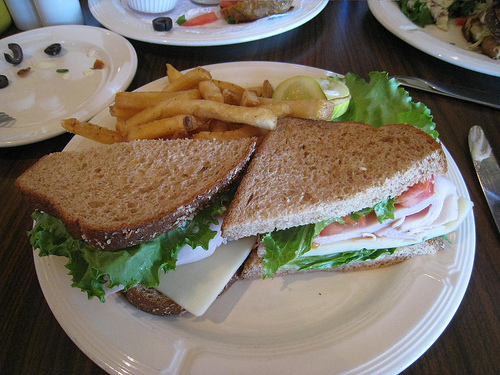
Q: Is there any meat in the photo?
A: Yes, there is meat.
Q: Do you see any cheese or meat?
A: Yes, there is meat.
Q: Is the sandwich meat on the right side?
A: Yes, the meat is on the right of the image.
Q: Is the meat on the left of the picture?
A: No, the meat is on the right of the image.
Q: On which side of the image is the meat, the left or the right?
A: The meat is on the right of the image.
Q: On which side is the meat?
A: The meat is on the right of the image.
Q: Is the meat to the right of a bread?
A: Yes, the meat is to the right of a bread.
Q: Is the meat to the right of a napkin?
A: No, the meat is to the right of a bread.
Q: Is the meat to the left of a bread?
A: No, the meat is to the right of a bread.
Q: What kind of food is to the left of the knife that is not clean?
A: The food is meat.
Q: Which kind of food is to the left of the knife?
A: The food is meat.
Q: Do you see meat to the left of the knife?
A: Yes, there is meat to the left of the knife.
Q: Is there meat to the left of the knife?
A: Yes, there is meat to the left of the knife.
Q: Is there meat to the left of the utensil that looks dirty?
A: Yes, there is meat to the left of the knife.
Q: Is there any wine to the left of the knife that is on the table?
A: No, there is meat to the left of the knife.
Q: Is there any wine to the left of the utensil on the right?
A: No, there is meat to the left of the knife.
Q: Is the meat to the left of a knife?
A: Yes, the meat is to the left of a knife.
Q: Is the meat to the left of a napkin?
A: No, the meat is to the left of a knife.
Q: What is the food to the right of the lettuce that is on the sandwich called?
A: The food is meat.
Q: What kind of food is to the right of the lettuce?
A: The food is meat.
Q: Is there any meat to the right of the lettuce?
A: Yes, there is meat to the right of the lettuce.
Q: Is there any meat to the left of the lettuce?
A: No, the meat is to the right of the lettuce.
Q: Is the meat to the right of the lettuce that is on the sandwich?
A: Yes, the meat is to the right of the lettuce.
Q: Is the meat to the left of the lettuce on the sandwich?
A: No, the meat is to the right of the lettuce.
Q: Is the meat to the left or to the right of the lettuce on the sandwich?
A: The meat is to the right of the lettuce.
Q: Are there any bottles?
A: No, there are no bottles.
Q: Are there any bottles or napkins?
A: No, there are no bottles or napkins.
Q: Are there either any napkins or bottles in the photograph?
A: No, there are no bottles or napkins.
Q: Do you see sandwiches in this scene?
A: Yes, there is a sandwich.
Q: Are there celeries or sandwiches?
A: Yes, there is a sandwich.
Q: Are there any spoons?
A: No, there are no spoons.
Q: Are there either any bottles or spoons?
A: No, there are no spoons or bottles.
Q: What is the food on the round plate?
A: The food is a sandwich.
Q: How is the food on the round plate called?
A: The food is a sandwich.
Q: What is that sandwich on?
A: The sandwich is on the plate.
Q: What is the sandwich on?
A: The sandwich is on the plate.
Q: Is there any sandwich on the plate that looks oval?
A: Yes, there is a sandwich on the plate.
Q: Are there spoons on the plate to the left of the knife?
A: No, there is a sandwich on the plate.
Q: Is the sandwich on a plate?
A: Yes, the sandwich is on a plate.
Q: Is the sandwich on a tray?
A: No, the sandwich is on a plate.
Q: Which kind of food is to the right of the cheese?
A: The food is a sandwich.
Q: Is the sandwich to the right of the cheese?
A: Yes, the sandwich is to the right of the cheese.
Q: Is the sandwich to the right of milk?
A: No, the sandwich is to the right of the cheese.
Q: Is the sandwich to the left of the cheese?
A: No, the sandwich is to the right of the cheese.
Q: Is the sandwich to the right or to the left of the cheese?
A: The sandwich is to the right of the cheese.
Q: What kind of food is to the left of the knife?
A: The food is a sandwich.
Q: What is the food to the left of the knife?
A: The food is a sandwich.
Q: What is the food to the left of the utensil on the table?
A: The food is a sandwich.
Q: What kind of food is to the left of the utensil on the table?
A: The food is a sandwich.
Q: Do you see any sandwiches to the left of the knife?
A: Yes, there is a sandwich to the left of the knife.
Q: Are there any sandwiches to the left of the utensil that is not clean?
A: Yes, there is a sandwich to the left of the knife.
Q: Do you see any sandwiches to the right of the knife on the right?
A: No, the sandwich is to the left of the knife.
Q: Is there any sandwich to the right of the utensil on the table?
A: No, the sandwich is to the left of the knife.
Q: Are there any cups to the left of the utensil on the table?
A: No, there is a sandwich to the left of the knife.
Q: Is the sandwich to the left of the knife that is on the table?
A: Yes, the sandwich is to the left of the knife.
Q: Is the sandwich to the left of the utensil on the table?
A: Yes, the sandwich is to the left of the knife.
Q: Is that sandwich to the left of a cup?
A: No, the sandwich is to the left of the knife.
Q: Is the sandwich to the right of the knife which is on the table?
A: No, the sandwich is to the left of the knife.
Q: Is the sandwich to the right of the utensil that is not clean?
A: No, the sandwich is to the left of the knife.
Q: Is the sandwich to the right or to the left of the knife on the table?
A: The sandwich is to the left of the knife.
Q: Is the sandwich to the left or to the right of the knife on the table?
A: The sandwich is to the left of the knife.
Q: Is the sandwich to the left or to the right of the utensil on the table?
A: The sandwich is to the left of the knife.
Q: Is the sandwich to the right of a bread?
A: Yes, the sandwich is to the right of a bread.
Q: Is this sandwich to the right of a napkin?
A: No, the sandwich is to the right of a bread.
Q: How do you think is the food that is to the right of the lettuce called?
A: The food is a sandwich.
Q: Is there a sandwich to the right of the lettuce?
A: Yes, there is a sandwich to the right of the lettuce.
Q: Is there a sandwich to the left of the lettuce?
A: No, the sandwich is to the right of the lettuce.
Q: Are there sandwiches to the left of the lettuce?
A: No, the sandwich is to the right of the lettuce.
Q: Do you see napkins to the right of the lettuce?
A: No, there is a sandwich to the right of the lettuce.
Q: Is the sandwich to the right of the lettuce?
A: Yes, the sandwich is to the right of the lettuce.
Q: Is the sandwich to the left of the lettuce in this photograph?
A: No, the sandwich is to the right of the lettuce.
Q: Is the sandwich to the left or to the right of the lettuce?
A: The sandwich is to the right of the lettuce.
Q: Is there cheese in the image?
A: Yes, there is cheese.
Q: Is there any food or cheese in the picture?
A: Yes, there is cheese.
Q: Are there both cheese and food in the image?
A: Yes, there are both cheese and food.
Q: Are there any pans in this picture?
A: No, there are no pans.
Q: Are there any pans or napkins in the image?
A: No, there are no pans or napkins.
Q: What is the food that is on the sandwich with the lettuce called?
A: The food is cheese.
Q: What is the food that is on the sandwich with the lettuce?
A: The food is cheese.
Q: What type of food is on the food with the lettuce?
A: The food is cheese.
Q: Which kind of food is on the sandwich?
A: The food is cheese.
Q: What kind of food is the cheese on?
A: The cheese is on the sandwich.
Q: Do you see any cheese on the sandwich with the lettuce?
A: Yes, there is cheese on the sandwich.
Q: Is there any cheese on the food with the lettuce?
A: Yes, there is cheese on the sandwich.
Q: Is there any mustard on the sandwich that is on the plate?
A: No, there is cheese on the sandwich.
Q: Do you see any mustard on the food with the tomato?
A: No, there is cheese on the sandwich.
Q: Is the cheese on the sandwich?
A: Yes, the cheese is on the sandwich.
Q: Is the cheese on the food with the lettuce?
A: Yes, the cheese is on the sandwich.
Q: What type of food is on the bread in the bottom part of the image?
A: The food is cheese.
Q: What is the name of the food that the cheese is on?
A: The food is a bread.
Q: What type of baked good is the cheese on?
A: The cheese is on the bread.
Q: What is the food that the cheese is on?
A: The food is a bread.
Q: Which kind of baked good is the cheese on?
A: The cheese is on the bread.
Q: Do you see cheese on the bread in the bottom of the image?
A: Yes, there is cheese on the bread.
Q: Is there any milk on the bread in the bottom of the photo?
A: No, there is cheese on the bread.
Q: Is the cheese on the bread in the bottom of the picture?
A: Yes, the cheese is on the bread.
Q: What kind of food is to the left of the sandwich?
A: The food is cheese.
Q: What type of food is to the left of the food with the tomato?
A: The food is cheese.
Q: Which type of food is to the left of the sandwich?
A: The food is cheese.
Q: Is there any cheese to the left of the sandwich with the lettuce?
A: Yes, there is cheese to the left of the sandwich.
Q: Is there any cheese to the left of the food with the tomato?
A: Yes, there is cheese to the left of the sandwich.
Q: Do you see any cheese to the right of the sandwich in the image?
A: No, the cheese is to the left of the sandwich.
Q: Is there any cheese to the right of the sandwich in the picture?
A: No, the cheese is to the left of the sandwich.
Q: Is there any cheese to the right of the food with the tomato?
A: No, the cheese is to the left of the sandwich.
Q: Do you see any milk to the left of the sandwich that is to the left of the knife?
A: No, there is cheese to the left of the sandwich.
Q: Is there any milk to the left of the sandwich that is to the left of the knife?
A: No, there is cheese to the left of the sandwich.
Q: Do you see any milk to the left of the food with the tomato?
A: No, there is cheese to the left of the sandwich.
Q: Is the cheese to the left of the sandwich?
A: Yes, the cheese is to the left of the sandwich.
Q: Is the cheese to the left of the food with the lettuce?
A: Yes, the cheese is to the left of the sandwich.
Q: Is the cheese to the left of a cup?
A: No, the cheese is to the left of the sandwich.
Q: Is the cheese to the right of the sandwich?
A: No, the cheese is to the left of the sandwich.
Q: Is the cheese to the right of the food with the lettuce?
A: No, the cheese is to the left of the sandwich.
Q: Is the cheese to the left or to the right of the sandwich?
A: The cheese is to the left of the sandwich.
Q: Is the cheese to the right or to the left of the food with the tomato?
A: The cheese is to the left of the sandwich.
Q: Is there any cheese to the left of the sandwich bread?
A: Yes, there is cheese to the left of the bread.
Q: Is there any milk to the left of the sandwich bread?
A: No, there is cheese to the left of the bread.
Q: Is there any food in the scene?
A: Yes, there is food.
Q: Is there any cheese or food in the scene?
A: Yes, there is food.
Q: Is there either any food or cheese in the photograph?
A: Yes, there is food.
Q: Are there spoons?
A: No, there are no spoons.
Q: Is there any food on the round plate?
A: Yes, there is food on the plate.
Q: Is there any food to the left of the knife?
A: Yes, there is food to the left of the knife.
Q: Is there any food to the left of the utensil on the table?
A: Yes, there is food to the left of the knife.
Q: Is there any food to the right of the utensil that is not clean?
A: No, the food is to the left of the knife.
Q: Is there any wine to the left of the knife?
A: No, there is food to the left of the knife.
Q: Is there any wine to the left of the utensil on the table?
A: No, there is food to the left of the knife.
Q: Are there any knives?
A: Yes, there is a knife.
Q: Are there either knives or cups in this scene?
A: Yes, there is a knife.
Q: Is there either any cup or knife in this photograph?
A: Yes, there is a knife.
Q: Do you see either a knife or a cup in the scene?
A: Yes, there is a knife.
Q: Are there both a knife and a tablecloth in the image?
A: No, there is a knife but no tablecloths.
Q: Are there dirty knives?
A: Yes, there is a dirty knife.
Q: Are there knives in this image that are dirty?
A: Yes, there is a knife that is dirty.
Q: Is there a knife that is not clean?
A: Yes, there is a dirty knife.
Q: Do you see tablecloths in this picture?
A: No, there are no tablecloths.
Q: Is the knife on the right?
A: Yes, the knife is on the right of the image.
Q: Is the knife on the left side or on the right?
A: The knife is on the right of the image.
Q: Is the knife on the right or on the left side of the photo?
A: The knife is on the right of the image.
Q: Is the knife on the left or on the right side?
A: The knife is on the right of the image.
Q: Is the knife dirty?
A: Yes, the knife is dirty.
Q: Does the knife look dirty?
A: Yes, the knife is dirty.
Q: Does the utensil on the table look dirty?
A: Yes, the knife is dirty.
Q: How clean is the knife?
A: The knife is dirty.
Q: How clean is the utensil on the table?
A: The knife is dirty.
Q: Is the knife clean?
A: No, the knife is dirty.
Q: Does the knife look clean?
A: No, the knife is dirty.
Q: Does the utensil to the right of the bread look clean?
A: No, the knife is dirty.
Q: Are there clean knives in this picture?
A: No, there is a knife but it is dirty.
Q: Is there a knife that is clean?
A: No, there is a knife but it is dirty.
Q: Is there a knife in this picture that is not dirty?
A: No, there is a knife but it is dirty.